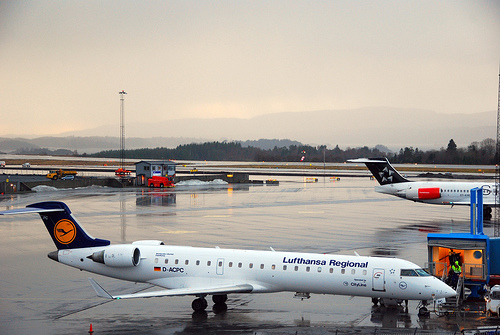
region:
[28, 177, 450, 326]
A plane at the terminal.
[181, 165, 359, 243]
The runway is wet.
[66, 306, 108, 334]
Orange cone on the pavement.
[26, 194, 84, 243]
The tail is gold and blue.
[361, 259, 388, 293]
Door on the plane.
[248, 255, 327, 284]
The plane has windows.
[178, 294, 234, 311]
The tires under the plane.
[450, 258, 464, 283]
A man walking down the steps.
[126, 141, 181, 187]
A building on the runway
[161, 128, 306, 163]
Trees in the background.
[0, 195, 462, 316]
a plan at the airport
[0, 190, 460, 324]
a white plane on the ground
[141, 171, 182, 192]
a red car at the airport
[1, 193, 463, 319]
a white plane that is parked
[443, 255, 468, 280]
an airport traffic control person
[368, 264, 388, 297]
the door to the plane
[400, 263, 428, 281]
the windshield for the plane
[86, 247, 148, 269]
the plane jet engine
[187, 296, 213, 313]
the wheels of the airplane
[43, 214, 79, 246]
the airline logo on the plane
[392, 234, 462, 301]
front of a plane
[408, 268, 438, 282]
window of a plane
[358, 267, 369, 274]
window of a plane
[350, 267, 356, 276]
window of a plane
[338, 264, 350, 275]
window of a plane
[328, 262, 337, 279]
window of a plane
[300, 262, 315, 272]
window of a plane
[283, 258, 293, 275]
window of a plane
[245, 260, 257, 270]
window of a plane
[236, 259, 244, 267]
window of a plane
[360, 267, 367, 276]
small window on plane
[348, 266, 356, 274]
small window on plane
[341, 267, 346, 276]
small window on plane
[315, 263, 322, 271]
small window on plane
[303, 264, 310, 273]
small window on plane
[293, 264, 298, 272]
small window on plane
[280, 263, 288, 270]
small window on plane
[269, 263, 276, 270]
small window on plane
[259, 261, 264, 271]
small window on plane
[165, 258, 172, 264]
small window on plane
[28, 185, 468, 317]
this is a plane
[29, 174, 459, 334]
plane parked on the tarmac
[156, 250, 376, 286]
windows on the plane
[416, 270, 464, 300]
nose of the plane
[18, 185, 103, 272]
tail of the plane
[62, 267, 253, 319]
wing on the plane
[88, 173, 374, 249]
the tarmac is wet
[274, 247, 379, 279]
blue writing on plane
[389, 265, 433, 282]
front window on plane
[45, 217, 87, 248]
orange decal on plane tail